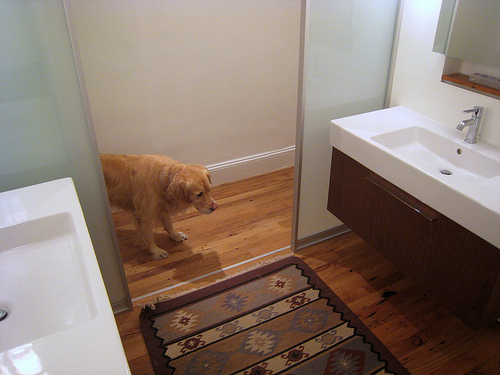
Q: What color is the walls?
A: White.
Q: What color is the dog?
A: Brown.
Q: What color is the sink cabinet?
A: Dark Brown.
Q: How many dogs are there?
A: One.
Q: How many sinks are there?
A: Two.